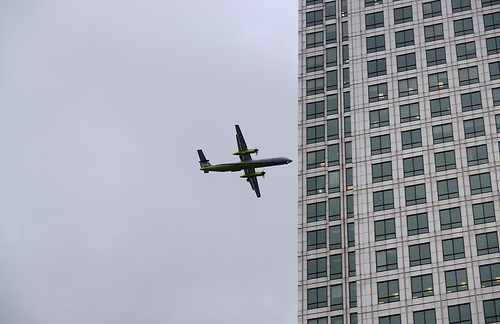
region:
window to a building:
[433, 262, 473, 305]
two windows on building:
[399, 266, 477, 301]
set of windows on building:
[360, 228, 476, 304]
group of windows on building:
[356, 138, 490, 312]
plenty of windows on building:
[358, 98, 474, 302]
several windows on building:
[365, 98, 480, 304]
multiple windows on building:
[363, 76, 468, 302]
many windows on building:
[365, 76, 470, 308]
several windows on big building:
[360, 84, 489, 301]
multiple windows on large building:
[366, 29, 478, 309]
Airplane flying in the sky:
[196, 119, 292, 197]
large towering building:
[300, 3, 499, 320]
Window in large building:
[369, 163, 395, 183]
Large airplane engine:
[233, 146, 261, 158]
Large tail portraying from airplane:
[193, 141, 215, 181]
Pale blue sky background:
[30, 118, 84, 208]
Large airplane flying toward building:
[188, 121, 295, 216]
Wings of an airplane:
[228, 120, 271, 210]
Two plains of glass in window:
[369, 163, 394, 183]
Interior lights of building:
[374, 80, 451, 100]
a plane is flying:
[162, 110, 374, 258]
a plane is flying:
[140, 114, 494, 298]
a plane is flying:
[137, 92, 312, 209]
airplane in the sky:
[175, 106, 296, 203]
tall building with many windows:
[292, 1, 499, 322]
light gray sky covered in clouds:
[2, 1, 299, 322]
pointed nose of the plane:
[286, 153, 297, 166]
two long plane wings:
[227, 116, 274, 205]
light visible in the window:
[393, 288, 400, 298]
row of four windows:
[365, 139, 492, 189]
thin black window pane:
[384, 278, 391, 302]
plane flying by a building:
[184, 111, 365, 213]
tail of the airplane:
[196, 141, 212, 177]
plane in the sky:
[165, 67, 310, 204]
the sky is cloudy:
[33, 85, 210, 322]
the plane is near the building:
[223, 94, 267, 201]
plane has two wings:
[221, 105, 270, 224]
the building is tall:
[295, 39, 488, 289]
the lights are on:
[354, 81, 499, 114]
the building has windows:
[298, 58, 480, 322]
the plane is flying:
[123, 122, 320, 228]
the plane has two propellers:
[234, 134, 284, 214]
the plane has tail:
[179, 131, 250, 210]